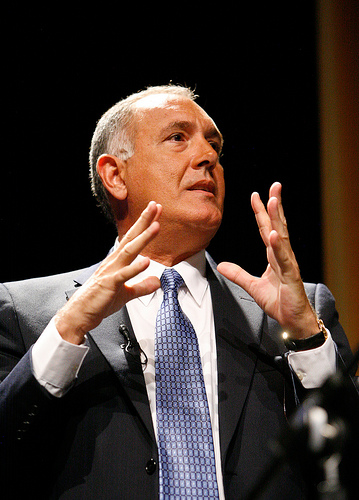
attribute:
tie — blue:
[148, 267, 243, 479]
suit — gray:
[0, 234, 357, 498]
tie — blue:
[145, 256, 270, 488]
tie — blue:
[160, 277, 193, 346]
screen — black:
[27, 17, 356, 248]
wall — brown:
[315, 11, 355, 351]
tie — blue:
[153, 267, 219, 497]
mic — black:
[114, 319, 158, 399]